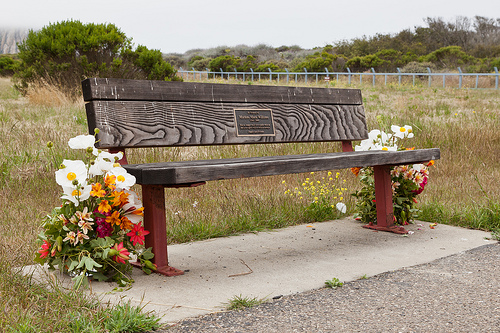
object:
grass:
[0, 85, 497, 333]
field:
[0, 75, 500, 333]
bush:
[6, 19, 194, 103]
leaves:
[61, 244, 165, 286]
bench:
[81, 77, 440, 277]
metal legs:
[143, 170, 426, 279]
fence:
[177, 65, 499, 88]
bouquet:
[35, 134, 156, 293]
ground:
[417, 157, 433, 178]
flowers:
[355, 123, 435, 237]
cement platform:
[14, 214, 500, 326]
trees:
[0, 16, 500, 103]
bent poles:
[176, 66, 500, 89]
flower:
[282, 172, 347, 210]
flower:
[336, 202, 347, 214]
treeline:
[166, 16, 497, 73]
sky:
[0, 0, 499, 57]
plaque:
[234, 108, 276, 137]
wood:
[78, 72, 442, 187]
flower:
[37, 133, 152, 279]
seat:
[77, 77, 444, 272]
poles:
[176, 65, 500, 88]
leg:
[130, 184, 187, 276]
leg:
[362, 164, 409, 234]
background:
[0, 13, 499, 83]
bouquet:
[351, 124, 436, 228]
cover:
[88, 6, 475, 77]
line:
[185, 68, 321, 78]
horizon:
[9, 47, 492, 87]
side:
[80, 78, 172, 267]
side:
[357, 87, 410, 234]